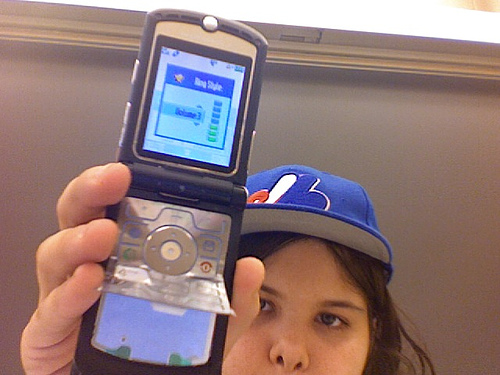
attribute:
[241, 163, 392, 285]
hat — blue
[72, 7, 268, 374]
phone — flip, black, bent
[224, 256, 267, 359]
thumb — finger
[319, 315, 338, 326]
eye — blue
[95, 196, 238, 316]
pad — silver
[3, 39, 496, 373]
wall — brown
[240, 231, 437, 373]
hair — brown, dark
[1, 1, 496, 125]
roof — lighted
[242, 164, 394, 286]
cap — blue, white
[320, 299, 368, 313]
eyebrow — dark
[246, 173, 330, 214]
logo — blue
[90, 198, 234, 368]
keypad — broken